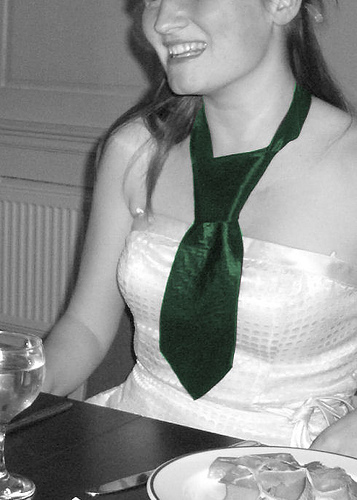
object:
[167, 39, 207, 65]
mouth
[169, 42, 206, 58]
teeth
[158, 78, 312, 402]
tie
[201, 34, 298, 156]
neck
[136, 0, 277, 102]
face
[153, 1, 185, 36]
nose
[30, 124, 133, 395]
arm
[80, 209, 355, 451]
white dress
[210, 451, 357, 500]
meat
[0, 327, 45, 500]
glass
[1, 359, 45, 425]
water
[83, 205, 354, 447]
dress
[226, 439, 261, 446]
handle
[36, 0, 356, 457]
female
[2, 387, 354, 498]
table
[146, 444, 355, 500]
plate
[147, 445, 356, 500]
white plate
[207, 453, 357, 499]
food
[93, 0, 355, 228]
hair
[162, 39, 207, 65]
smile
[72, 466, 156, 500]
butter knife